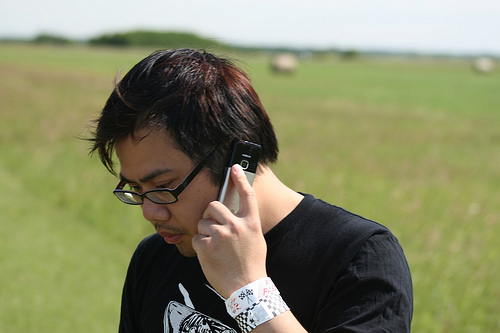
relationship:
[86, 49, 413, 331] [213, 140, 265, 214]
man on cellphone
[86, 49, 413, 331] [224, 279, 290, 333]
man wearing bracelet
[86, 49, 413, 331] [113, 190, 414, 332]
man wearing shirt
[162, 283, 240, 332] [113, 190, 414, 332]
drawing on shirt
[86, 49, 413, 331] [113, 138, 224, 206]
man wearing glasses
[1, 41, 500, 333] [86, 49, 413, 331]
field behind man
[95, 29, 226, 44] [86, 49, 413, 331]
hill behind man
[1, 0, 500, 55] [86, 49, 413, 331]
sky behind man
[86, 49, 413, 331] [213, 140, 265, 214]
man holding cellphone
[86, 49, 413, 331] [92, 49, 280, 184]
man has hair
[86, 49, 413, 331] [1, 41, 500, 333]
man in field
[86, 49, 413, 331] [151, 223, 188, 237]
man has moustache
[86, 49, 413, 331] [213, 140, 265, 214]
man listening on cellphone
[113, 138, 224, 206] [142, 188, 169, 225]
glasses are resting on nose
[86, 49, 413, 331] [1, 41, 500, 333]
man in front of field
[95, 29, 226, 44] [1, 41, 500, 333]
hill in field